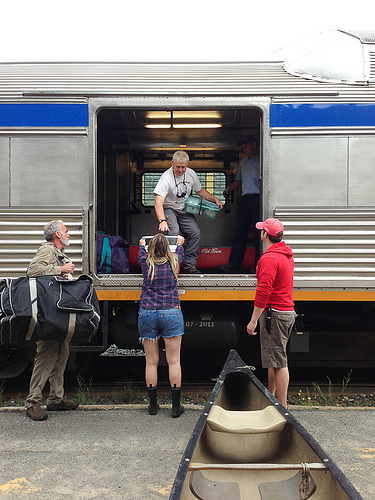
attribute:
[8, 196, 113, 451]
man — carrying, wearing, holding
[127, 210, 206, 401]
woman — wearing, reaching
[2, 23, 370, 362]
train — platform, blue, black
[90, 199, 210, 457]
person — wearing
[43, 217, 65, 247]
hair — grey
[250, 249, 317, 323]
coat — red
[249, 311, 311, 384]
short — colored, cut off, man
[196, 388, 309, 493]
boat — small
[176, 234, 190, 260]
trim — white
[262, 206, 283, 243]
cap — red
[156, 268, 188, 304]
shirt — plaid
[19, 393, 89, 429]
shoe — brown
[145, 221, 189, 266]
container — blue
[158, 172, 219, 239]
strap — neck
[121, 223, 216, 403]
lady — wearing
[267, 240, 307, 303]
sweater — red, back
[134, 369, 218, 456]
boot — brown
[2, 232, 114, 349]
bag — big, purple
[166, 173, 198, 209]
glass — in the picture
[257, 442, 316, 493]
rope — attached